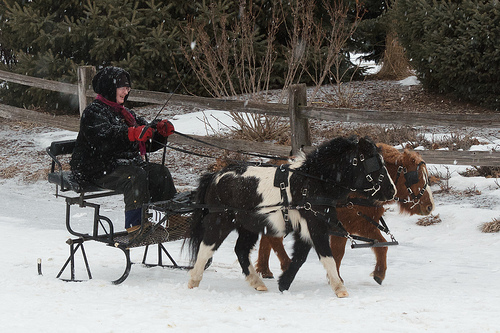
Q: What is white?
A: Snow.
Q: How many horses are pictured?
A: Two.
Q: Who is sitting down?
A: A person.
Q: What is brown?
A: One horse.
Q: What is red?
A: Person's gloves.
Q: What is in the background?
A: Trees.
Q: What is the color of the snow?
A: White.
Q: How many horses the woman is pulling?
A: Two.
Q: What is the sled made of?
A: Metal.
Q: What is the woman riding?
A: A carriage.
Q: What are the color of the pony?
A: Black and white.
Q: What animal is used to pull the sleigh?
A: Ponies.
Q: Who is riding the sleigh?
A: A woman.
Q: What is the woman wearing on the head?
A: A winter hat.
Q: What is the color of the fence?
A: Brown.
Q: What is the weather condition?
A: It is snowing.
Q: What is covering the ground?
A: Snow.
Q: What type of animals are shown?
A: Ponies.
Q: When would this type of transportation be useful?
A: Winter.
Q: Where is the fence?
A: Behind the sleigh.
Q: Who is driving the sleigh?
A: An older woman.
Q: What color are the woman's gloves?
A: Red.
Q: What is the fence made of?
A: Wood.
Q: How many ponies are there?
A: 2.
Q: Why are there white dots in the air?
A: It's snowing.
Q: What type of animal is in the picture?
A: Ponies.